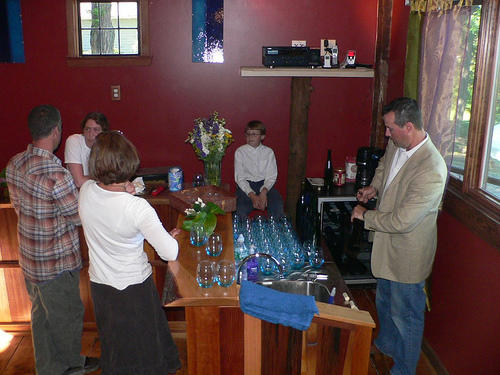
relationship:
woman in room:
[78, 132, 179, 374] [2, 1, 499, 375]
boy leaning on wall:
[233, 120, 285, 222] [1, 0, 385, 144]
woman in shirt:
[78, 132, 179, 374] [78, 179, 181, 291]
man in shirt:
[6, 102, 88, 353] [5, 144, 87, 274]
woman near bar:
[64, 111, 108, 188] [164, 177, 375, 340]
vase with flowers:
[201, 159, 224, 191] [185, 110, 234, 158]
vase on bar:
[201, 159, 224, 191] [164, 177, 375, 340]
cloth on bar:
[236, 279, 318, 331] [164, 177, 375, 340]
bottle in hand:
[351, 192, 364, 254] [350, 203, 367, 222]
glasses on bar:
[189, 214, 326, 287] [164, 177, 375, 340]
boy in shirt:
[233, 120, 285, 222] [234, 144, 280, 193]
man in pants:
[351, 98, 448, 339] [374, 273, 427, 372]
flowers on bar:
[185, 110, 234, 158] [164, 177, 375, 340]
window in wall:
[79, 2, 138, 54] [1, 0, 385, 144]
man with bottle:
[351, 98, 448, 339] [351, 192, 364, 254]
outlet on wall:
[110, 84, 122, 103] [1, 0, 385, 144]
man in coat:
[351, 98, 448, 339] [365, 132, 449, 277]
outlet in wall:
[110, 84, 122, 103] [1, 0, 385, 144]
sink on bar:
[246, 275, 336, 301] [164, 177, 375, 340]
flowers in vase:
[185, 110, 234, 158] [201, 159, 224, 191]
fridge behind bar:
[303, 177, 380, 286] [164, 177, 375, 340]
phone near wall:
[331, 44, 341, 66] [1, 0, 385, 144]